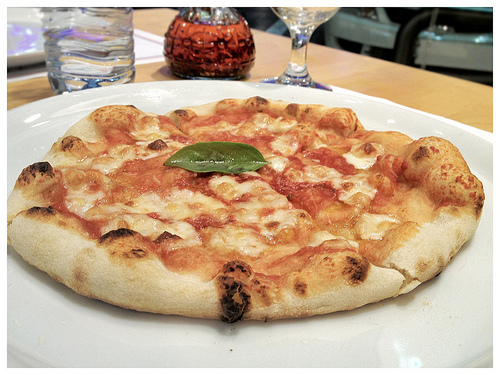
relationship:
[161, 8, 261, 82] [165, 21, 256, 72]
bottle with amber liquid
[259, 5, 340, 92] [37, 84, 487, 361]
glass behind plate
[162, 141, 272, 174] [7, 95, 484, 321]
basil leaf in pie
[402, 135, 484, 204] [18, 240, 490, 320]
bubbles on crust with crust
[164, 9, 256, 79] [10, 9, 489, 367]
goblet on table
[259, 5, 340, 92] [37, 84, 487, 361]
glass by plate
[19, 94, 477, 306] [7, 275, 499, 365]
pizza on plate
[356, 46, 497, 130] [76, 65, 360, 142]
table under plate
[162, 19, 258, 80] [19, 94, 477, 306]
liquid behind pizza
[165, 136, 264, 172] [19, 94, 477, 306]
leaf on pizza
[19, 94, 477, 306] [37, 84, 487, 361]
pizza on plate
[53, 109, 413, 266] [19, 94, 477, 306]
cheese on pizza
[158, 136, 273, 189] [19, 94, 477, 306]
basil on pizza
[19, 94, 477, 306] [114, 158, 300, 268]
pizza has cheese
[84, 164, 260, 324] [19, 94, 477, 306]
section of pizza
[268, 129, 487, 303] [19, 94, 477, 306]
section of pizza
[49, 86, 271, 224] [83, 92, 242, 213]
section of pizza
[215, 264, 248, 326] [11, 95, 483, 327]
bubble of crust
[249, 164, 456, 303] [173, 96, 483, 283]
cut separating slice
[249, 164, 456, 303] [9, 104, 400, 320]
cut separating slice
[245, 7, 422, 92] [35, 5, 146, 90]
bottle of bottled water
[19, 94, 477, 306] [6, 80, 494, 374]
pizza on plate